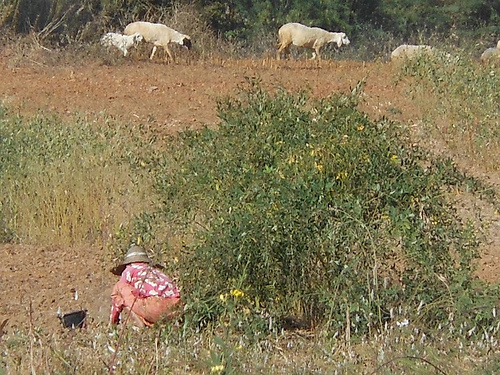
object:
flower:
[227, 286, 243, 303]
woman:
[104, 243, 181, 338]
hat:
[108, 241, 163, 274]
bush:
[142, 78, 497, 343]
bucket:
[56, 308, 89, 329]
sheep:
[95, 29, 146, 60]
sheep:
[121, 20, 196, 60]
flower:
[393, 316, 411, 330]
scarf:
[111, 259, 182, 297]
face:
[181, 36, 195, 52]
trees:
[251, 2, 355, 55]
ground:
[0, 53, 497, 374]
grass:
[6, 290, 496, 373]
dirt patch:
[0, 236, 122, 325]